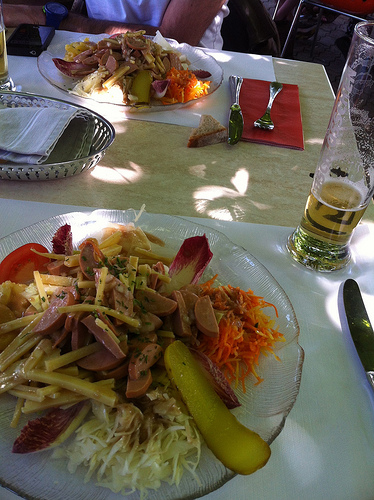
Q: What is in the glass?
A: A drink.